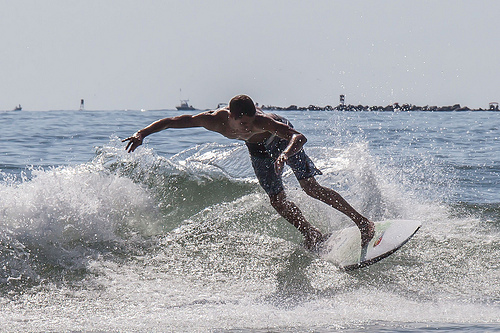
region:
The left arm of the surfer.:
[150, 106, 210, 131]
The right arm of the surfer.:
[262, 117, 300, 144]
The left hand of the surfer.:
[127, 134, 147, 151]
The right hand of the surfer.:
[269, 147, 289, 176]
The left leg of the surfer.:
[271, 191, 316, 238]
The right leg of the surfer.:
[305, 171, 365, 223]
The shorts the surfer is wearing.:
[247, 137, 315, 189]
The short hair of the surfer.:
[226, 90, 256, 122]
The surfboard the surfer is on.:
[311, 217, 414, 267]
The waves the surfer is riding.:
[83, 141, 450, 291]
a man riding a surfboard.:
[110, 85, 376, 276]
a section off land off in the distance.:
[0, 92, 497, 109]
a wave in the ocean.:
[0, 131, 495, 331]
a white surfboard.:
[288, 186, 439, 290]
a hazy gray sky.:
[3, 0, 496, 117]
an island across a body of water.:
[204, 100, 498, 108]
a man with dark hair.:
[221, 97, 271, 127]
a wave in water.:
[0, 128, 499, 328]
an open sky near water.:
[0, 0, 499, 117]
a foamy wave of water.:
[0, 161, 498, 327]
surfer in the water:
[117, 50, 392, 261]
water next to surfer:
[180, 245, 260, 290]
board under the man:
[301, 201, 426, 281]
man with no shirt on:
[195, 66, 345, 231]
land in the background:
[317, 86, 407, 141]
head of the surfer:
[213, 78, 276, 144]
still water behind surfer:
[437, 121, 484, 163]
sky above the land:
[251, 33, 320, 78]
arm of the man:
[111, 108, 214, 172]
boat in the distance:
[5, 85, 46, 132]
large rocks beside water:
[346, 94, 481, 115]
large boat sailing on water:
[173, 82, 203, 113]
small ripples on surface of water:
[29, 116, 86, 155]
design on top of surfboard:
[367, 225, 394, 252]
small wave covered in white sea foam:
[106, 271, 197, 326]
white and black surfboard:
[264, 206, 428, 283]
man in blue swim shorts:
[130, 74, 321, 207]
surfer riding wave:
[130, 85, 442, 285]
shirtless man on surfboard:
[124, 74, 431, 261]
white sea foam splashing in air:
[10, 157, 107, 238]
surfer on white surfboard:
[81, 80, 415, 281]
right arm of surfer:
[108, 115, 211, 141]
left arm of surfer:
[253, 113, 304, 180]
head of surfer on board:
[223, 96, 258, 131]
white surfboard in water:
[298, 217, 424, 264]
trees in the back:
[295, 86, 455, 111]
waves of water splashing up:
[337, 138, 402, 205]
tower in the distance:
[68, 91, 88, 109]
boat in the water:
[167, 95, 195, 111]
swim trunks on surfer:
[242, 141, 324, 195]